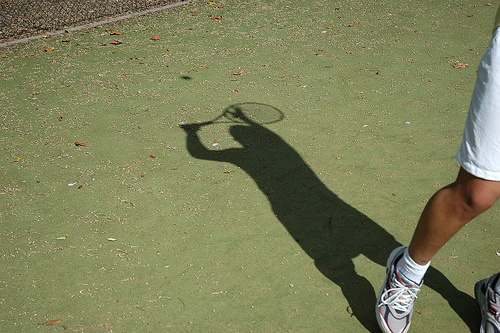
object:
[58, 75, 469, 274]
tennis court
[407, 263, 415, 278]
white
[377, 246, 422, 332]
shoe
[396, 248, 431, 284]
sock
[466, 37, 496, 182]
shorts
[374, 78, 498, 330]
leg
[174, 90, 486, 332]
shadow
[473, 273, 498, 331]
shoe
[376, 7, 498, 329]
person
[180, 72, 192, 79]
shadow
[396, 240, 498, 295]
socks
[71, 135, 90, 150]
leaf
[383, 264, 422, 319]
laces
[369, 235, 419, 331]
shoes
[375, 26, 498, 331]
tennis player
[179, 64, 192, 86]
ball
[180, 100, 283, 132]
tennis racket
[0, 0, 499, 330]
ground